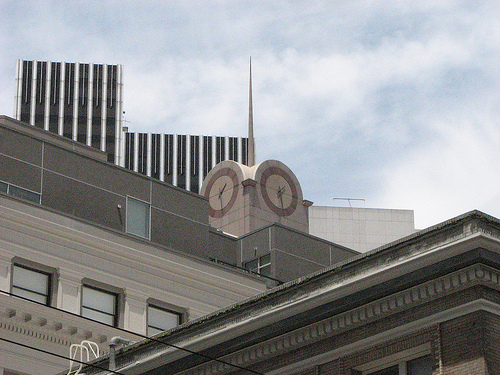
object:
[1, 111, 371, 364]
building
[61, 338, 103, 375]
ladder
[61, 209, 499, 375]
building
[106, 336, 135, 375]
pipe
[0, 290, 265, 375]
wires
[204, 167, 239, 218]
clock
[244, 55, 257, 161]
spire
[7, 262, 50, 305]
windows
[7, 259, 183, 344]
row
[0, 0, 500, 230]
sky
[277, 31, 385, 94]
clouds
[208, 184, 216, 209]
left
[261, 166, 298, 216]
clock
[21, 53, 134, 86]
top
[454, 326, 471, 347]
brick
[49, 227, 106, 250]
paint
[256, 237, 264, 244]
bricks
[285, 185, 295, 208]
right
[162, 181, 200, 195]
edge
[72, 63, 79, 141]
lines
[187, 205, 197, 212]
brick